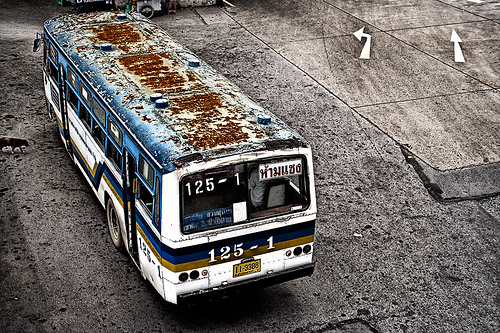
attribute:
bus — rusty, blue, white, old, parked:
[23, 28, 363, 305]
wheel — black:
[88, 205, 135, 249]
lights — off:
[180, 260, 201, 285]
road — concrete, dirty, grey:
[304, 128, 494, 306]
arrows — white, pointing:
[330, 23, 494, 73]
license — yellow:
[227, 246, 270, 286]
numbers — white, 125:
[187, 176, 248, 202]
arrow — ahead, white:
[427, 23, 466, 68]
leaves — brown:
[94, 1, 259, 149]